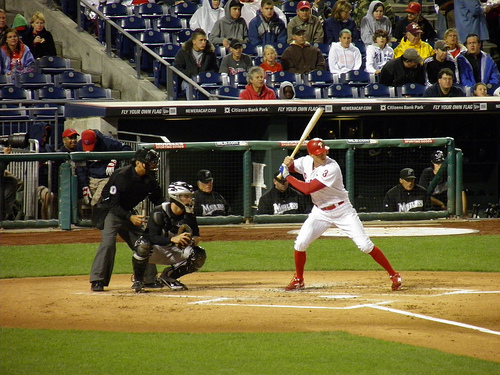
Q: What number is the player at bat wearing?
A: Number 3.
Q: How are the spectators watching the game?
A: They are sitting.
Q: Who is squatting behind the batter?
A: The Catcher.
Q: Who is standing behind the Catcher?
A: The Umpire.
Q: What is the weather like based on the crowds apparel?
A: Cold.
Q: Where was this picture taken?
A: At a baseball game.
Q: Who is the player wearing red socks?
A: The batter.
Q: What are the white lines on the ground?
A: The baselines and batters box.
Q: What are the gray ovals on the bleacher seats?
A: The seat numbers.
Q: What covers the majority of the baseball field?
A: Green grass.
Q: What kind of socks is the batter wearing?
A: Knee high.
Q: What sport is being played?
A: Baseball.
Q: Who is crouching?
A: Catcher.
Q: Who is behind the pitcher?
A: Umpire.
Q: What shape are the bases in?
A: Diamond.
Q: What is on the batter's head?
A: Helmet.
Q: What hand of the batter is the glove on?
A: Left.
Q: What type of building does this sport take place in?
A: Stadium.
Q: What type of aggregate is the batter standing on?
A: Dirt.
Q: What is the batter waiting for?
A: The ball.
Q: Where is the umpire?
A: Behind the catcher.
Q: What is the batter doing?
A: Waiting on the pitch.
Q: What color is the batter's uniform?
A: White and red.